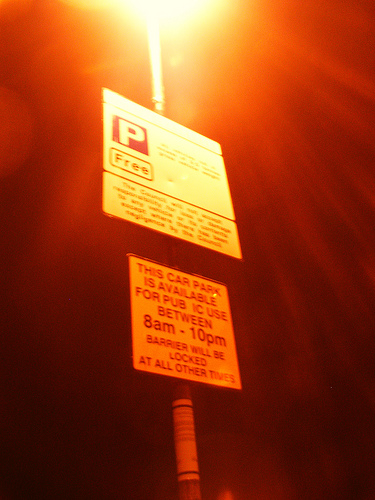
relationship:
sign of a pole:
[91, 84, 249, 265] [131, 8, 174, 94]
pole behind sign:
[131, 8, 174, 94] [91, 84, 249, 265]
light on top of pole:
[112, 1, 214, 30] [131, 8, 174, 94]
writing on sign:
[125, 250, 240, 391] [91, 84, 249, 265]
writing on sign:
[119, 243, 346, 433] [91, 84, 249, 265]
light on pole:
[142, 9, 167, 109] [131, 8, 174, 94]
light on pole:
[112, 1, 214, 30] [146, 343, 274, 497]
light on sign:
[112, 1, 214, 30] [124, 233, 298, 421]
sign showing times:
[91, 84, 249, 265] [100, 287, 280, 364]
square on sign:
[63, 71, 286, 272] [91, 84, 249, 265]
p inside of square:
[81, 54, 194, 197] [49, 44, 317, 266]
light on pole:
[112, 1, 214, 30] [157, 378, 242, 496]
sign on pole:
[91, 84, 249, 265] [143, 366, 264, 497]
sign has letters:
[91, 84, 249, 265] [112, 254, 296, 393]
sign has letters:
[91, 84, 249, 265] [94, 237, 327, 392]